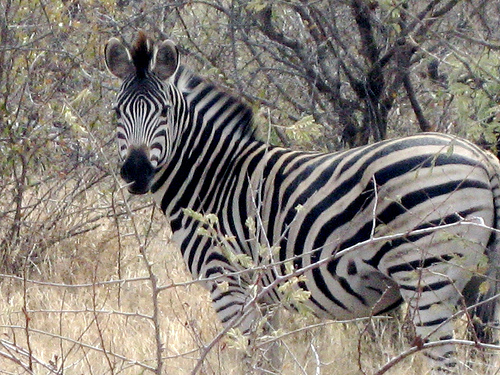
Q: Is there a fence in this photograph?
A: No, there are no fences.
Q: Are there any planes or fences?
A: No, there are no fences or planes.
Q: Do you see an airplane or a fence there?
A: No, there are no fences or airplanes.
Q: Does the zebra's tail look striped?
A: Yes, the tail is striped.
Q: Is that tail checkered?
A: No, the tail is striped.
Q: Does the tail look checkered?
A: No, the tail is striped.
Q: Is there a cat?
A: No, there are no cats.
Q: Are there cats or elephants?
A: No, there are no cats or elephants.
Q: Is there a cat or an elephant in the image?
A: No, there are no cats or elephants.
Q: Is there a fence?
A: No, there are no fences.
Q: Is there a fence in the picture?
A: No, there are no fences.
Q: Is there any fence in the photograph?
A: No, there are no fences.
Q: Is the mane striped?
A: Yes, the mane is striped.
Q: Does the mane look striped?
A: Yes, the mane is striped.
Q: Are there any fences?
A: No, there are no fences.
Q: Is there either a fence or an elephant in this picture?
A: No, there are no fences or elephants.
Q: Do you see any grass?
A: Yes, there is grass.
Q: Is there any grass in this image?
A: Yes, there is grass.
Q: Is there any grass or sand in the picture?
A: Yes, there is grass.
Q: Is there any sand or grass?
A: Yes, there is grass.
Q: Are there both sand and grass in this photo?
A: No, there is grass but no sand.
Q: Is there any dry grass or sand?
A: Yes, there is dry grass.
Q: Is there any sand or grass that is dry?
A: Yes, the grass is dry.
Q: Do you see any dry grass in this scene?
A: Yes, there is dry grass.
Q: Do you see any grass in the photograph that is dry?
A: Yes, there is grass that is dry.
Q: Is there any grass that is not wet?
A: Yes, there is dry grass.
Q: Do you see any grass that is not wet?
A: Yes, there is dry grass.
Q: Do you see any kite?
A: No, there are no kites.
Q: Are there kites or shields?
A: No, there are no kites or shields.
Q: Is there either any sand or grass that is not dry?
A: No, there is grass but it is dry.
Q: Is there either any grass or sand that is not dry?
A: No, there is grass but it is dry.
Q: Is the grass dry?
A: Yes, the grass is dry.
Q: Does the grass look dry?
A: Yes, the grass is dry.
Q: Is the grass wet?
A: No, the grass is dry.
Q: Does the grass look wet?
A: No, the grass is dry.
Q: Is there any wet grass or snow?
A: No, there is grass but it is dry.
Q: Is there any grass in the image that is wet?
A: No, there is grass but it is dry.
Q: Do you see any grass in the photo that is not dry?
A: No, there is grass but it is dry.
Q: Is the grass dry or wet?
A: The grass is dry.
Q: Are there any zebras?
A: Yes, there is a zebra.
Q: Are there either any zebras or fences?
A: Yes, there is a zebra.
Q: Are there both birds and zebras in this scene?
A: No, there is a zebra but no birds.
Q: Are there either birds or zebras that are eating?
A: Yes, the zebra is eating.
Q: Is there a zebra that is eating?
A: Yes, there is a zebra that is eating.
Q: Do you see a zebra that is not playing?
A: Yes, there is a zebra that is eating .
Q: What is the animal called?
A: The animal is a zebra.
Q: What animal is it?
A: The animal is a zebra.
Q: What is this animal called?
A: This is a zebra.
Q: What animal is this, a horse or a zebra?
A: This is a zebra.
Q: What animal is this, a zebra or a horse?
A: This is a zebra.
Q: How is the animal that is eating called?
A: The animal is a zebra.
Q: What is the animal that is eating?
A: The animal is a zebra.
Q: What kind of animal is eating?
A: The animal is a zebra.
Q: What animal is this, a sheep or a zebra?
A: This is a zebra.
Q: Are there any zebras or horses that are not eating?
A: No, there is a zebra but it is eating.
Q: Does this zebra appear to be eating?
A: Yes, the zebra is eating.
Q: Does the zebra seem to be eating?
A: Yes, the zebra is eating.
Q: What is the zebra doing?
A: The zebra is eating.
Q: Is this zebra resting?
A: No, the zebra is eating.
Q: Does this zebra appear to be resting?
A: No, the zebra is eating.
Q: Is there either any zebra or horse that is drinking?
A: No, there is a zebra but it is eating.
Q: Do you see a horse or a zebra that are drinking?
A: No, there is a zebra but it is eating.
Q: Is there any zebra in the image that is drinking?
A: No, there is a zebra but it is eating.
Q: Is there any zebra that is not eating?
A: No, there is a zebra but it is eating.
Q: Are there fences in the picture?
A: No, there are no fences.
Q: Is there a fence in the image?
A: No, there are no fences.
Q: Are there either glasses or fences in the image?
A: No, there are no fences or glasses.